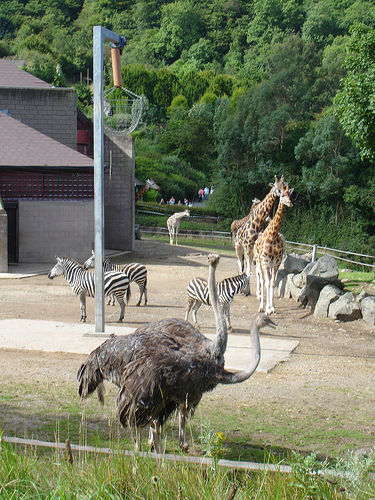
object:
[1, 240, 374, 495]
ground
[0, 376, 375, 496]
grass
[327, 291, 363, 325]
stones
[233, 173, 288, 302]
giraffes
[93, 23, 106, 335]
pole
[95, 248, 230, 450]
ostriches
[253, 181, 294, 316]
giraffes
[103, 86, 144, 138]
basket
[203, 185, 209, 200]
people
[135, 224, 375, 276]
fence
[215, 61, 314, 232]
trees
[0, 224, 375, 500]
enclosure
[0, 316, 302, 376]
pad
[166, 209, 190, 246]
giraffe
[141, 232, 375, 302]
grass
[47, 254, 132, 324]
zebras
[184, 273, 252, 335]
zebra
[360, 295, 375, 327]
rocks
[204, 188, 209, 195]
shirt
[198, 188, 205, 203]
woman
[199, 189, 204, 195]
shirt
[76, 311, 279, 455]
ostriches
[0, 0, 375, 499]
weather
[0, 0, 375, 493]
zoo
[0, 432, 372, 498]
fence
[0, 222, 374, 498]
pen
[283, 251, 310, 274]
rocks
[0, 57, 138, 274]
building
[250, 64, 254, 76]
leaves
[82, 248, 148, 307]
zebra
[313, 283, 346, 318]
rocks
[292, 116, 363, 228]
trees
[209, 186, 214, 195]
people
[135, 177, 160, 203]
giraffe